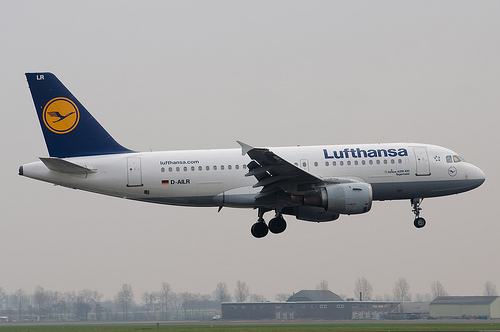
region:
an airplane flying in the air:
[13, 63, 485, 240]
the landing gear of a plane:
[409, 201, 426, 233]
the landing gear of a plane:
[267, 208, 287, 237]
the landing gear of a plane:
[249, 210, 271, 240]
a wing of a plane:
[238, 137, 320, 193]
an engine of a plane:
[301, 180, 377, 217]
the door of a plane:
[411, 143, 436, 178]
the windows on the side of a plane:
[317, 157, 409, 165]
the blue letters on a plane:
[320, 143, 410, 158]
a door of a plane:
[121, 150, 146, 191]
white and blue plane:
[16, 72, 486, 239]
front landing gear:
[407, 197, 427, 227]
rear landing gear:
[248, 207, 288, 237]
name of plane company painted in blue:
[322, 148, 409, 160]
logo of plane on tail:
[42, 96, 78, 133]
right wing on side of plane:
[231, 139, 320, 209]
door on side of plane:
[414, 146, 432, 175]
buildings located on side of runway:
[218, 289, 498, 322]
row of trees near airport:
[1, 278, 498, 318]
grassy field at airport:
[0, 323, 497, 330]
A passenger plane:
[7, 62, 491, 244]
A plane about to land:
[8, 66, 490, 245]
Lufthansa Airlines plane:
[12, 61, 490, 256]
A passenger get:
[12, 58, 492, 243]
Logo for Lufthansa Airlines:
[37, 93, 85, 135]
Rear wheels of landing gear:
[245, 197, 294, 242]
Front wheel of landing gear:
[402, 187, 434, 237]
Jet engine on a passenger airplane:
[307, 167, 382, 219]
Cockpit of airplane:
[432, 142, 489, 203]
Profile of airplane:
[15, 62, 489, 244]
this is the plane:
[18, 110, 473, 222]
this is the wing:
[225, 136, 291, 186]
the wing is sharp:
[231, 135, 311, 207]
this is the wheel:
[410, 210, 432, 230]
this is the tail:
[12, 71, 94, 146]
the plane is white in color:
[195, 163, 225, 185]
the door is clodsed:
[123, 156, 139, 186]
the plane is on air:
[13, 133, 480, 238]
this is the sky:
[233, 8, 380, 100]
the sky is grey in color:
[245, 63, 305, 93]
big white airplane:
[12, 69, 488, 207]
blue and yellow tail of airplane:
[21, 70, 133, 156]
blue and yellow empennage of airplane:
[23, 67, 132, 154]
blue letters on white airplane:
[318, 142, 407, 169]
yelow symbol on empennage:
[36, 94, 81, 131]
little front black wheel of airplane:
[407, 201, 428, 231]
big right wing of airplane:
[236, 139, 332, 211]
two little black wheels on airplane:
[241, 212, 287, 239]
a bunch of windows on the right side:
[157, 153, 411, 176]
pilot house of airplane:
[446, 150, 463, 169]